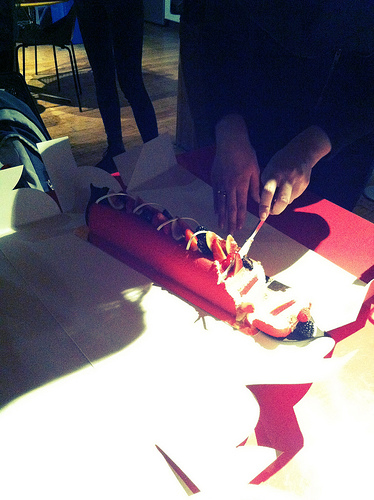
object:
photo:
[0, 0, 373, 500]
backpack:
[0, 90, 61, 212]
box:
[0, 131, 374, 498]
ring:
[216, 189, 228, 197]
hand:
[209, 124, 262, 237]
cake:
[86, 183, 315, 340]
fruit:
[297, 303, 312, 322]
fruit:
[286, 318, 314, 341]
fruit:
[172, 219, 186, 242]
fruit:
[226, 234, 239, 255]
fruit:
[185, 228, 199, 253]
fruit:
[134, 195, 146, 216]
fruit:
[206, 229, 218, 252]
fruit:
[108, 188, 125, 211]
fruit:
[196, 225, 214, 259]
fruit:
[242, 256, 254, 273]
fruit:
[233, 254, 244, 277]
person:
[178, 1, 374, 237]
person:
[73, 0, 158, 175]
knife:
[217, 217, 267, 286]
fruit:
[212, 241, 227, 262]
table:
[0, 147, 373, 496]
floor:
[16, 20, 183, 167]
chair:
[14, 1, 82, 113]